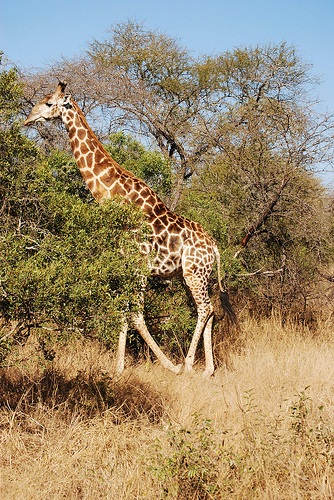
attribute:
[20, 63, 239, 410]
giraffe — brown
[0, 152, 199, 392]
bush — thorny, green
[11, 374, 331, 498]
grass — dry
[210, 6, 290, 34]
sky — blue, clear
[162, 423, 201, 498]
plant — green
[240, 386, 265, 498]
plant — green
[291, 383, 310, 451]
plant — green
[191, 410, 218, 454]
plant — green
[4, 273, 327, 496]
grass — dying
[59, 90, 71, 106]
ear — white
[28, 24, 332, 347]
tree — tall, thin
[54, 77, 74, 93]
horns — short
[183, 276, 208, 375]
leg — long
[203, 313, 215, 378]
leg — long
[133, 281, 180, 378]
leg — long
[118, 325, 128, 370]
leg — long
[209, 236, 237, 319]
tail — long, thin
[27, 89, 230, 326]
giraffe — white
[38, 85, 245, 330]
giraffe — brown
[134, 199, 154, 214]
spots — mosaic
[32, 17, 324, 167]
sky — blue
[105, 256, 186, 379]
legs — longer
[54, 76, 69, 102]
ossicles — brown, black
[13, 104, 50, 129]
nose — brown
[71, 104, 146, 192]
mane — short, brown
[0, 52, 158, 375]
tree — green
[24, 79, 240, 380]
giraffe — spotted, grazing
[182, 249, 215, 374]
legs — back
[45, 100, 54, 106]
eye — gentle, dark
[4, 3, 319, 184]
sky — blue